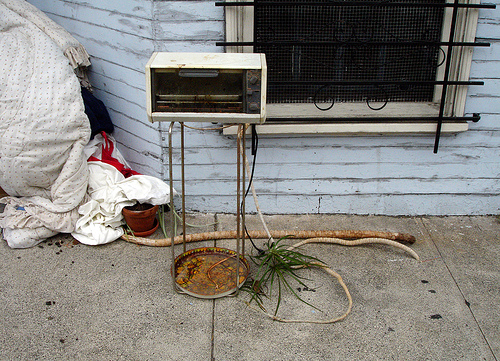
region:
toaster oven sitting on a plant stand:
[141, 46, 269, 301]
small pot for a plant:
[119, 195, 167, 242]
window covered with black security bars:
[230, 0, 478, 145]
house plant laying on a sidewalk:
[236, 220, 328, 324]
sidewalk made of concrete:
[26, 257, 148, 347]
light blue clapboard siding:
[350, 142, 452, 212]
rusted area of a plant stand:
[168, 240, 252, 302]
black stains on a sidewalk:
[406, 267, 466, 359]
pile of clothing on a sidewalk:
[5, 5, 118, 250]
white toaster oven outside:
[139, 42, 279, 127]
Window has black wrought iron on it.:
[211, 2, 492, 157]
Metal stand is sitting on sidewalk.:
[163, 122, 252, 297]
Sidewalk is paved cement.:
[1, 200, 498, 358]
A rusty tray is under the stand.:
[167, 242, 249, 307]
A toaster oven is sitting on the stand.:
[143, 45, 273, 127]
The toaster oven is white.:
[143, 45, 270, 132]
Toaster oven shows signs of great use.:
[142, 46, 273, 133]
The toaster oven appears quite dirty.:
[143, 47, 265, 129]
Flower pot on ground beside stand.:
[117, 197, 164, 237]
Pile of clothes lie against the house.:
[1, 2, 173, 253]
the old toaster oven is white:
[133, 43, 274, 148]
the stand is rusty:
[143, 108, 265, 297]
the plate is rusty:
[157, 241, 258, 301]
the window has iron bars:
[211, 2, 490, 127]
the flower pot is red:
[98, 192, 166, 246]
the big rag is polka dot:
[6, 35, 96, 252]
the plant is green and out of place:
[248, 230, 330, 333]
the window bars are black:
[203, 1, 498, 161]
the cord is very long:
[241, 127, 425, 357]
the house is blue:
[174, 125, 485, 216]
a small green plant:
[246, 229, 322, 298]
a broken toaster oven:
[136, 44, 293, 146]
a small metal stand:
[149, 104, 288, 285]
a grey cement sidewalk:
[38, 256, 498, 356]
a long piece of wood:
[166, 222, 420, 251]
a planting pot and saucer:
[115, 191, 172, 243]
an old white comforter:
[0, 31, 125, 256]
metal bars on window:
[226, 34, 485, 148]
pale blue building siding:
[280, 145, 470, 203]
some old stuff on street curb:
[17, 9, 462, 328]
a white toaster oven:
[143, 48, 268, 125]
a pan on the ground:
[168, 243, 250, 300]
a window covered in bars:
[213, 0, 495, 141]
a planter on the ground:
[120, 202, 162, 238]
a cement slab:
[212, 212, 498, 359]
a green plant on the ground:
[248, 232, 331, 319]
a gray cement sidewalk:
[1, 211, 497, 359]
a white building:
[25, 0, 499, 215]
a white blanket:
[0, 0, 93, 252]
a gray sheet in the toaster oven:
[154, 87, 245, 102]